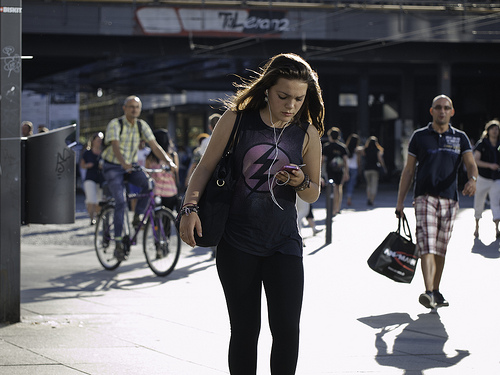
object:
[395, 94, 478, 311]
man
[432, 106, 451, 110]
glasses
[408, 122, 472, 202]
shirt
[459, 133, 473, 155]
sleeve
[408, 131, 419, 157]
sleeve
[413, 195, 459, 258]
shorts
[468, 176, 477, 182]
watch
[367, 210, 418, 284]
bag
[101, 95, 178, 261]
man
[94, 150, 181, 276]
bike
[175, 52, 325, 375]
girl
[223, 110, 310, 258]
shirt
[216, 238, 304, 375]
leggings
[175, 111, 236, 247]
purse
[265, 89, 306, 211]
earphones